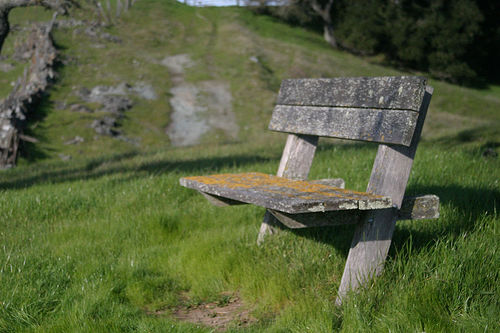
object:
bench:
[179, 71, 433, 312]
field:
[0, 1, 500, 331]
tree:
[305, 2, 341, 53]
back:
[0, 0, 500, 164]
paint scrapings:
[287, 195, 395, 215]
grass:
[0, 137, 498, 332]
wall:
[0, 14, 73, 167]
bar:
[329, 141, 419, 311]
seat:
[179, 170, 395, 215]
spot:
[163, 287, 261, 328]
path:
[163, 38, 241, 148]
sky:
[173, 0, 296, 13]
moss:
[179, 173, 378, 198]